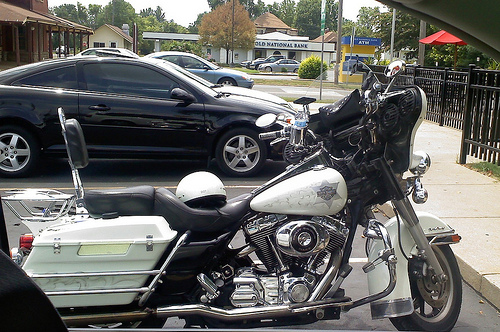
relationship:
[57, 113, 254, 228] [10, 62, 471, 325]
seat on motorcycle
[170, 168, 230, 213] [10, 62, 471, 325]
helmet on motorcycle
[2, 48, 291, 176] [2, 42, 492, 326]
car in lot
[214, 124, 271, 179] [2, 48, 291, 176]
wheel on car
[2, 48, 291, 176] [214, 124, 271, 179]
car has wheel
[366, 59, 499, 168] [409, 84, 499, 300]
fence by sidewalk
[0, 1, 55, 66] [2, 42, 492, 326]
building by lot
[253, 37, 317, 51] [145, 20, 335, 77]
writing on building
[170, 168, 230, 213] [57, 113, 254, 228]
helmet on seat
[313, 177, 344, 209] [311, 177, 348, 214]
star has points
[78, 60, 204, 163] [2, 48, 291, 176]
door on car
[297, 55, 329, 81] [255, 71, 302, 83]
bush by sidewalk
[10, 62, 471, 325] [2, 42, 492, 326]
motorcycle in lot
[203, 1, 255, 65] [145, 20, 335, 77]
tree by building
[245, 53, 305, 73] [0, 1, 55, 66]
cars by building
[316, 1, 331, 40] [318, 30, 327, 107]
sign on pole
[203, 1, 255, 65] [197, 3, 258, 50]
tree has leaves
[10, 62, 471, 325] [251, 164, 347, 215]
motorcycle has tank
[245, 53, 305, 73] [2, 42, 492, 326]
cars in lot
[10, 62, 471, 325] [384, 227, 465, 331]
motorcycle has wheel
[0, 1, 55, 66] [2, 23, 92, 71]
building has porch